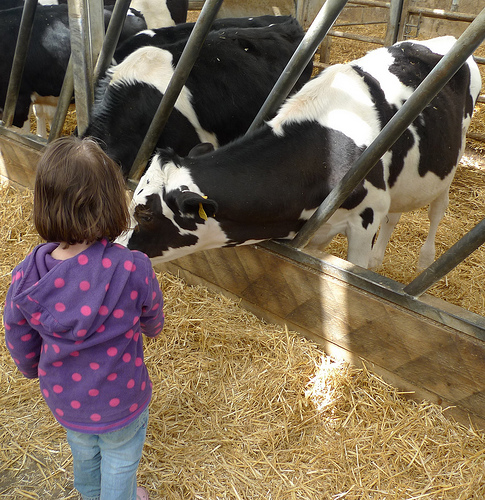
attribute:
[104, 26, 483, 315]
cow — white, black, in a shed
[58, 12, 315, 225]
cow — white, black, in a shed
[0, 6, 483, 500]
floor — covered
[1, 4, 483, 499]
hay — brown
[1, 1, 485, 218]
gate — metal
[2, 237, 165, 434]
hoodie — purple, pink, dotten, with pink dots, polka dot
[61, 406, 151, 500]
jeans — girl's, blue, pair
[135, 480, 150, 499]
shoe — pink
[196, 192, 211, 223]
tag — yellow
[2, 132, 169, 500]
girl — young, feeding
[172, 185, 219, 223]
ear — black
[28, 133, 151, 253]
hair — brown